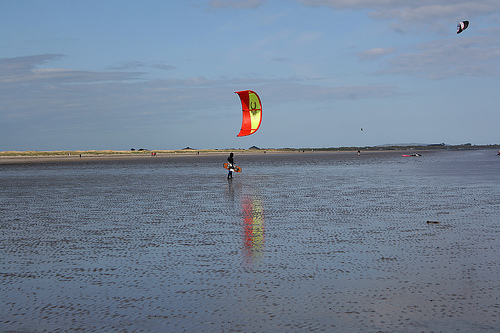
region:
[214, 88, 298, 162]
the kite is orange and red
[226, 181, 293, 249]
the reflection is on the sea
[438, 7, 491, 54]
the kite is in the air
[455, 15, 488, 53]
the kite is black and white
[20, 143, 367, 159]
people are in the distance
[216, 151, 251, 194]
the guy is holding a surfboard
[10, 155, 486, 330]
the ground is wet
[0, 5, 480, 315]
the scene is outdoors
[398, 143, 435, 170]
kite is on the ground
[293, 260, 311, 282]
part of the ocean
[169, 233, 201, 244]
edge of a sea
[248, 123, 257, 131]
part of a kite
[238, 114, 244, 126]
edge of a kite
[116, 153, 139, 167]
part of a beach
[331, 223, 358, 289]
part of the shore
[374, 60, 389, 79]
part of a cloud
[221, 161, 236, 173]
part of a board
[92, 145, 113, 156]
part of a field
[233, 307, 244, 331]
part of the ocean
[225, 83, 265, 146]
yellow and red parasailing sail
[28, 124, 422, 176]
beach water and shore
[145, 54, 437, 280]
calm water with people inside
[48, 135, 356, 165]
beach full of people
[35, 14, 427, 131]
cloudy sky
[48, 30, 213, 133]
blue sky with thin clouds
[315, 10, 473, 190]
people parasailing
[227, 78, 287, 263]
person and sail with water reflecting them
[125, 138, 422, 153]
hills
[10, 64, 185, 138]
grey clouds in the sky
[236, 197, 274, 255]
reflection on water surface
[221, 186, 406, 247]
ripples on water surface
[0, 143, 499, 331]
wet sand on the beach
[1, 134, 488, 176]
shore line of beach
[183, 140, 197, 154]
sand dune on the beach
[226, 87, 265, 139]
man's kite in air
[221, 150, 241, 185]
man walking on sand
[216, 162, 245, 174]
man';s kite board in hand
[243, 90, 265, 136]
yellow design on kite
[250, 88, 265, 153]
curve of kite in the air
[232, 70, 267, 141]
A red and yellow kit.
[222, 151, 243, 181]
A man with an orange and white surf board.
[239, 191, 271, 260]
A reflection of the kit in No. 1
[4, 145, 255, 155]
The beach in the back ground of the man and kit.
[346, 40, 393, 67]
A big fluffy cloud.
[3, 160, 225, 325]
A big, blue ocean.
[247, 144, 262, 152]
A mountain behind the beach.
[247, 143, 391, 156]
People on the beach in the back ground.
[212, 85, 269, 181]
A person and a kit in the ocean.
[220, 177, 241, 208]
The reflection of the man with a surf board.